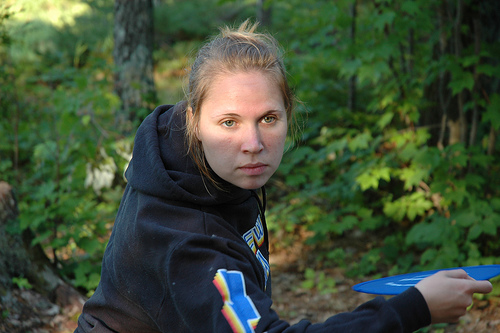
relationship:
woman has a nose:
[76, 23, 493, 332] [241, 119, 265, 157]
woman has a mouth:
[76, 23, 493, 332] [233, 161, 276, 175]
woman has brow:
[76, 23, 493, 332] [217, 111, 246, 119]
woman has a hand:
[76, 23, 493, 332] [412, 268, 494, 325]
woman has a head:
[76, 23, 493, 332] [183, 29, 291, 193]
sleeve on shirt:
[166, 234, 430, 333] [74, 101, 433, 331]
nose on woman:
[241, 119, 265, 157] [76, 23, 493, 332]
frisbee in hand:
[351, 263, 499, 296] [412, 268, 494, 325]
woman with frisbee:
[76, 23, 493, 332] [351, 263, 499, 296]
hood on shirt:
[123, 103, 245, 206] [74, 101, 433, 331]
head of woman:
[183, 29, 291, 193] [76, 23, 493, 332]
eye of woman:
[220, 119, 239, 129] [76, 23, 493, 332]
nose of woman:
[241, 119, 265, 157] [76, 23, 493, 332]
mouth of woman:
[233, 161, 276, 175] [76, 23, 493, 332]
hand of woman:
[412, 268, 494, 325] [76, 23, 493, 332]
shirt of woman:
[74, 101, 433, 331] [76, 23, 493, 332]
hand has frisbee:
[412, 268, 494, 325] [351, 263, 499, 296]